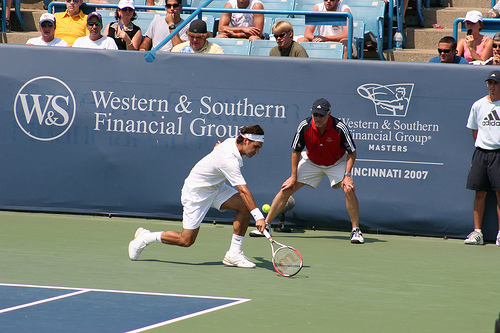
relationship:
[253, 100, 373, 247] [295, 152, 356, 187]
man wearing shorts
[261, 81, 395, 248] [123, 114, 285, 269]
man watching player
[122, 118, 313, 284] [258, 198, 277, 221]
tennis player hitting tennis ball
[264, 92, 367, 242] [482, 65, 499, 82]
man wearing hat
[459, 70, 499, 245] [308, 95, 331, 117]
man wearing hat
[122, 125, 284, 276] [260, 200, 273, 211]
man trying to hit tennis ball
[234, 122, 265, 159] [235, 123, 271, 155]
sweatband head around head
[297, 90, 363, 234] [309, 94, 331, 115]
man wearing baseball hat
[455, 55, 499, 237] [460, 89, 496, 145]
man wearing addidas t-shirt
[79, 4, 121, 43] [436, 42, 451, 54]
spectator wearing sunglasses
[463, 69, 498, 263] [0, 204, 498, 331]
man standing court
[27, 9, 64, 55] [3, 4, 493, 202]
man seated in stands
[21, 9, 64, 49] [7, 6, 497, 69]
man seated in stands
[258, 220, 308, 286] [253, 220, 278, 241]
racket in hand